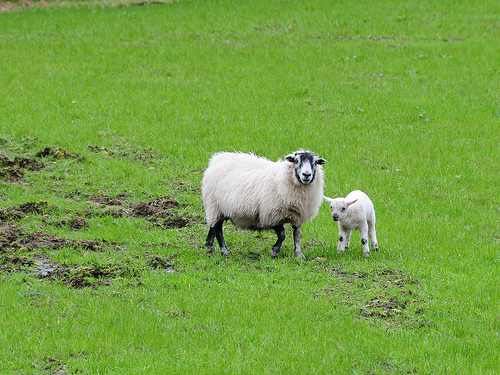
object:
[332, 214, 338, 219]
nose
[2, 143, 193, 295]
muddy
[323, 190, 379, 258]
baby lamb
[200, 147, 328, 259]
mother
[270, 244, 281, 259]
hooves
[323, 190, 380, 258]
baby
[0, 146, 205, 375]
hole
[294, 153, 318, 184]
face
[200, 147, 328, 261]
lamb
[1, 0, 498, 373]
ground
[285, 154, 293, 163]
ears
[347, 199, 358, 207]
ear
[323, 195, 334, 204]
ear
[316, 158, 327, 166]
ear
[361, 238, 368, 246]
patch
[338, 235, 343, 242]
patch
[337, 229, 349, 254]
leg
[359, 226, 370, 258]
leg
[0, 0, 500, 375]
grass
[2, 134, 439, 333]
dirt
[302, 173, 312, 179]
nose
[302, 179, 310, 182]
mouth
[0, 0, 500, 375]
area